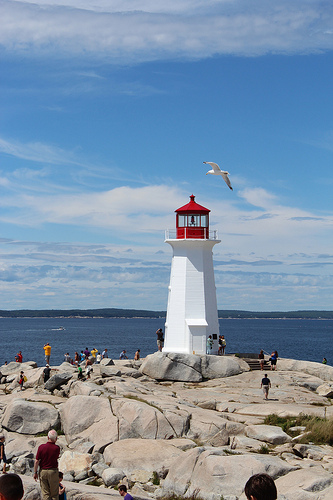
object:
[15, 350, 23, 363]
fat person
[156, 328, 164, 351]
man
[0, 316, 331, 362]
sea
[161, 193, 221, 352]
lighthouse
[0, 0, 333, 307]
clouds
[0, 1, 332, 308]
sky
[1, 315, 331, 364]
lake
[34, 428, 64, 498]
man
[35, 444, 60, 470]
red shirt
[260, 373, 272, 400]
man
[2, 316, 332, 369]
water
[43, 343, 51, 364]
fat man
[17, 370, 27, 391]
people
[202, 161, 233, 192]
bird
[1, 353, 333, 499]
boulders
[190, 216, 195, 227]
light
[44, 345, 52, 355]
shirt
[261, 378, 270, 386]
shirt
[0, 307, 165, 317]
treeline